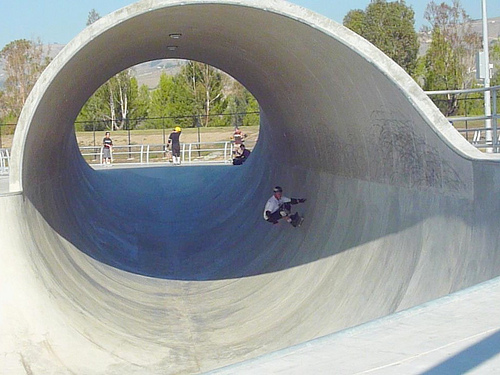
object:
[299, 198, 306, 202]
glove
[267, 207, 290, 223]
pant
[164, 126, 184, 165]
man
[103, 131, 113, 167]
man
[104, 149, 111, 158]
short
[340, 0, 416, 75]
tree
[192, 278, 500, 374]
surface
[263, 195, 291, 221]
shirt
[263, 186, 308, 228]
man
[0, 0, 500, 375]
cement structure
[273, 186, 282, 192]
safety helmet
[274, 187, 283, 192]
helmet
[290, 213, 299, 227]
skateboard